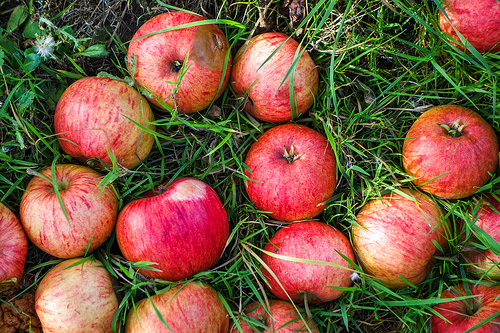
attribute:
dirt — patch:
[0, 294, 34, 331]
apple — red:
[228, 25, 323, 125]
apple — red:
[125, 7, 234, 111]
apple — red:
[60, 62, 156, 172]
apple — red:
[18, 157, 114, 259]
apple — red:
[106, 170, 238, 275]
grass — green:
[2, 0, 499, 332]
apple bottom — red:
[271, 142, 302, 169]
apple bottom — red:
[439, 115, 468, 140]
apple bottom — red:
[44, 173, 69, 193]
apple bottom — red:
[172, 52, 185, 74]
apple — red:
[399, 97, 491, 196]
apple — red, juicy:
[243, 119, 344, 230]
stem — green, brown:
[12, 167, 67, 184]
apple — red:
[243, 121, 337, 222]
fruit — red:
[47, 25, 339, 325]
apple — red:
[396, 105, 498, 205]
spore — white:
[25, 29, 62, 63]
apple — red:
[128, 8, 225, 114]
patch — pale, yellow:
[166, 177, 209, 203]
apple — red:
[114, 176, 235, 283]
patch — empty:
[334, 41, 429, 111]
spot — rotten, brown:
[189, 24, 229, 82]